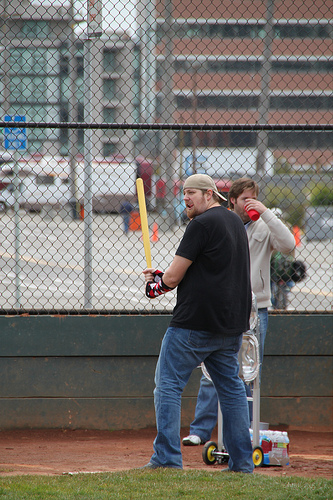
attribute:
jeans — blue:
[146, 322, 258, 474]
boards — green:
[3, 312, 332, 430]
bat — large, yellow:
[132, 173, 161, 283]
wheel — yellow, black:
[195, 433, 267, 470]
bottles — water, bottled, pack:
[251, 421, 298, 472]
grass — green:
[3, 465, 331, 499]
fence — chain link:
[5, 2, 330, 304]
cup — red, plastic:
[239, 203, 267, 222]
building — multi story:
[127, 1, 331, 175]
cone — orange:
[147, 218, 166, 246]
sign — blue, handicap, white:
[1, 114, 31, 153]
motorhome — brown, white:
[3, 151, 142, 220]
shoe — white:
[180, 432, 206, 449]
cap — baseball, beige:
[177, 170, 235, 202]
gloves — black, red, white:
[137, 265, 176, 301]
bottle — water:
[273, 426, 290, 467]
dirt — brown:
[2, 424, 330, 471]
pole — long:
[74, 5, 113, 165]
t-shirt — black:
[159, 199, 260, 338]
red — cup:
[243, 206, 262, 223]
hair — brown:
[225, 170, 272, 225]